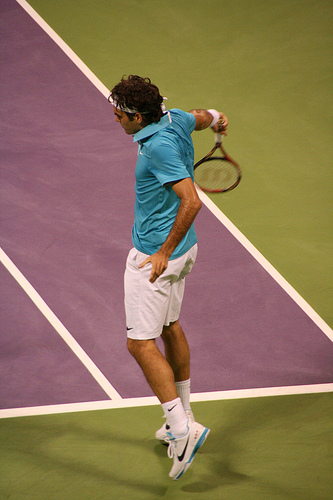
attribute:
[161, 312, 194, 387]
leg — bare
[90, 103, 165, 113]
sweatband — white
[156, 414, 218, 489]
shoes — white, sport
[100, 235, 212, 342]
shorts — nike, white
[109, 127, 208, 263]
shirt — short sleeved, polo, blue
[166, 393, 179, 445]
socks — nike, white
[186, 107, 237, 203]
racket — wilson, red, black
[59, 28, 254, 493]
player — male, person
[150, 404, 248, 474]
shoe — white, blue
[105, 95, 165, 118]
head band — white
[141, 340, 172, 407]
leg — bare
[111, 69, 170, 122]
hair — dark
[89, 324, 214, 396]
legs — tan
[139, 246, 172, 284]
hand — open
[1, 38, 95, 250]
turf — purple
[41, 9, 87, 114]
lines — white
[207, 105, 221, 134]
wristband — white